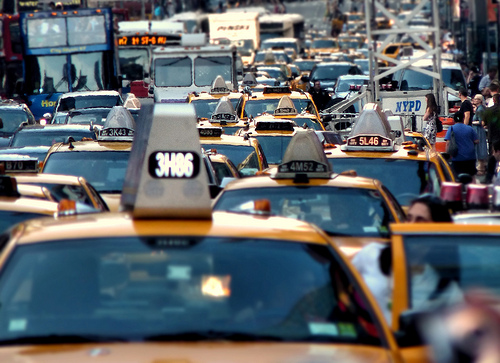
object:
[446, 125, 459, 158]
purse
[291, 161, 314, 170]
4m52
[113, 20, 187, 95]
bus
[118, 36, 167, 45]
numbers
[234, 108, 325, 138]
taxi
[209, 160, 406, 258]
taxi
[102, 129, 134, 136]
number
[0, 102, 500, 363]
cab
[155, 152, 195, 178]
numbers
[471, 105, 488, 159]
dress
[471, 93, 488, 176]
woman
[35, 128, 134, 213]
taxi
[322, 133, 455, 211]
taxi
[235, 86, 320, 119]
taxi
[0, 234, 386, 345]
window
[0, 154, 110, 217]
taxi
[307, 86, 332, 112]
shirt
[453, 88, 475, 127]
man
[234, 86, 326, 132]
taxi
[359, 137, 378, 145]
number 5l46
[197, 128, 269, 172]
taxi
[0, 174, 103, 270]
taxi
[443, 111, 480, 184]
woman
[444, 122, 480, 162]
shirt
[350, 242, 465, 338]
shirt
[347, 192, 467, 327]
lady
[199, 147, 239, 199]
taxi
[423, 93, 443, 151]
woman